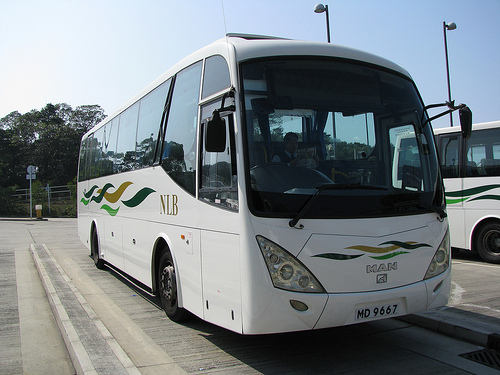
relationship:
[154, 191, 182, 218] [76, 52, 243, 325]
logo on side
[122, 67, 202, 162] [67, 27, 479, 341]
windows on right side of bus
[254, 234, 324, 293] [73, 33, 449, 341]
headlight on right side of bus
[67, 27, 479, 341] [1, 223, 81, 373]
bus on pavement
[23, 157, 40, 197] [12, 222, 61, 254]
sign in street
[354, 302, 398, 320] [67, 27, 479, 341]
plate on bus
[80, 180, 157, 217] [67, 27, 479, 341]
decorative design on bus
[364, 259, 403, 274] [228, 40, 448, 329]
logo on front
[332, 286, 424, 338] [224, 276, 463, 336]
plate on bottom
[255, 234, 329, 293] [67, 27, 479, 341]
headlight on bus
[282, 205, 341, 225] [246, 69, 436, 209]
wiper on window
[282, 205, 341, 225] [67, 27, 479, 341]
wiper on bus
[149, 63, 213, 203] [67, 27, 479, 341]
window on bus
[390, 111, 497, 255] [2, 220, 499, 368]
bus on pavement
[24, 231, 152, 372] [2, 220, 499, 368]
stripes on pavement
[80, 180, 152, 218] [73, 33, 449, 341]
decorative design on side of bus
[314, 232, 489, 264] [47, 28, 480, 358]
design on bus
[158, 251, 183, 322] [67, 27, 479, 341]
front wheel on bus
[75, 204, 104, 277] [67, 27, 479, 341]
wheel on bus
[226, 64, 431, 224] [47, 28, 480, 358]
windshield on front of bus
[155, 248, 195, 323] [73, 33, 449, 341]
front wheel on bus